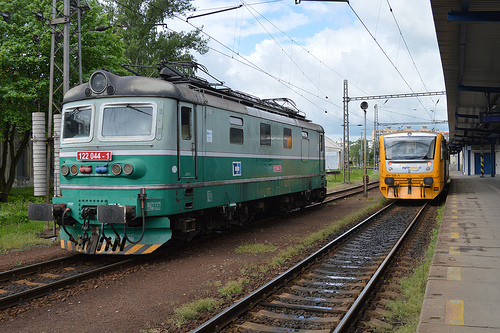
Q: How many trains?
A: Two.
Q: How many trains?
A: Two.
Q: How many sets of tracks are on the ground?
A: Two.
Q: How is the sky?
A: Cloudy.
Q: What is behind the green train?
A: Trees.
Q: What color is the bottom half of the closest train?
A: Green.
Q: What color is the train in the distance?
A: Yellow.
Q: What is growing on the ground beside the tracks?
A: Grass.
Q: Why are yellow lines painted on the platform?
A: For safety.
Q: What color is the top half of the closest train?
A: Grey.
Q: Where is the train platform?
A: Near the yellow train.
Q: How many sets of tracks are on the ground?
A: Two.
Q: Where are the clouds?
A: In the sky.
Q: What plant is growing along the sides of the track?
A: Grass.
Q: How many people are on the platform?
A: None.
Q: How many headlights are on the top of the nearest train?
A: One.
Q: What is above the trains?
A: Wires and cables.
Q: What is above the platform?
A: Roof.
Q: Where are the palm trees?
A: There are none.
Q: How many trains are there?
A: Two.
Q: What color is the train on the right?
A: Orange.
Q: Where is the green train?
A: Outside track.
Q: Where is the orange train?
A: Inside track.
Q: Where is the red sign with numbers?
A: On the front on the green train.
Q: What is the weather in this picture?
A: Cloudy.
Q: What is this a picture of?
A: Trains.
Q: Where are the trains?
A: On the tracks.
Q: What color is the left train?
A: Green.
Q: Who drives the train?
A: The conductor.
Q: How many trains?
A: Two.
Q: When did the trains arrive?
A: During the day.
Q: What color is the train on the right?
A: Yellow.